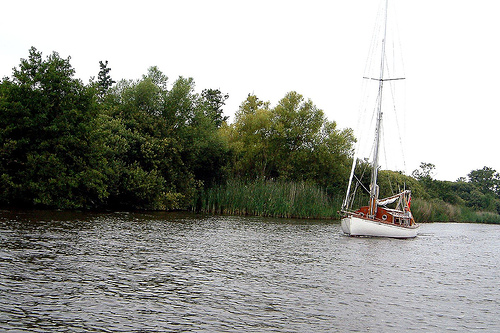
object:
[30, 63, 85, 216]
tree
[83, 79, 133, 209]
tree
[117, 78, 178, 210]
tree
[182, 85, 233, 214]
tree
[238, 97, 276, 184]
tree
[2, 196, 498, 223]
shore line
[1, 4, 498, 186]
clear sky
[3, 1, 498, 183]
white sky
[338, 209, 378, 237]
front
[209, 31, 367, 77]
sky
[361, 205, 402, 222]
frames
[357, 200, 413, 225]
cabins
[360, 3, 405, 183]
cross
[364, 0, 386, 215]
wires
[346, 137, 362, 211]
wires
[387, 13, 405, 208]
wires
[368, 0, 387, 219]
mast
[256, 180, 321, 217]
grass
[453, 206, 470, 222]
reeds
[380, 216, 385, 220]
windows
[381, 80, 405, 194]
lines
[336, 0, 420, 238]
boat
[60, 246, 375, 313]
lake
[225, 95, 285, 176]
trees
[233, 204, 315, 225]
bank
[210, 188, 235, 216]
reeds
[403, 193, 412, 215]
flag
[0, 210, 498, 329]
river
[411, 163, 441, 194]
trees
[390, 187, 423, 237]
back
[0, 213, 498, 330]
water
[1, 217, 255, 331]
ripples